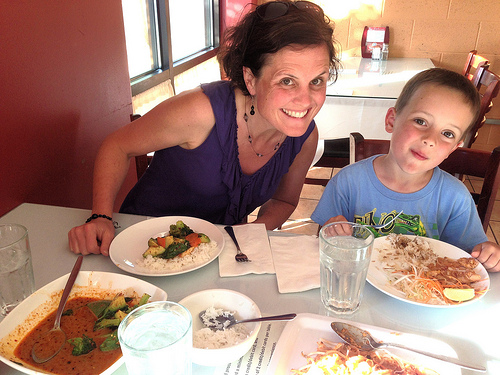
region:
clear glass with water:
[317, 217, 379, 319]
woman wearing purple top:
[82, 1, 332, 252]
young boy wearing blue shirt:
[310, 47, 498, 279]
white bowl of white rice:
[166, 285, 280, 368]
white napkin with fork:
[212, 219, 278, 280]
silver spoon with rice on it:
[192, 300, 305, 335]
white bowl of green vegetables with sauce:
[4, 263, 179, 373]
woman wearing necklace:
[67, 8, 354, 255]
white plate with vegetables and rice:
[107, 201, 234, 286]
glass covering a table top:
[288, 39, 455, 106]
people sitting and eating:
[0, 2, 485, 373]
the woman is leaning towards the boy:
[59, 3, 494, 286]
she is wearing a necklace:
[221, 84, 290, 174]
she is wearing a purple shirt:
[119, 74, 314, 223]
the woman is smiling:
[227, 0, 349, 137]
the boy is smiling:
[372, 59, 481, 181]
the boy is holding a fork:
[309, 191, 403, 247]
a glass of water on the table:
[318, 222, 375, 312]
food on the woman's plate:
[141, 217, 220, 271]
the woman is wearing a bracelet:
[80, 204, 119, 226]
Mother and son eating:
[88, 2, 495, 320]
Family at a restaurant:
[87, 5, 491, 322]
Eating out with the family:
[90, 7, 498, 322]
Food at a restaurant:
[5, 204, 495, 371]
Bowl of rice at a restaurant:
[162, 280, 303, 368]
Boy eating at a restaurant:
[300, 85, 499, 316]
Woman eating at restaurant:
[67, 2, 360, 285]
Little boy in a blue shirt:
[342, 55, 482, 237]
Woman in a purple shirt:
[92, 2, 332, 222]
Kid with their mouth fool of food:
[336, 62, 489, 241]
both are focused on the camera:
[203, 3, 463, 237]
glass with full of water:
[302, 217, 387, 313]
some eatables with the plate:
[390, 239, 475, 306]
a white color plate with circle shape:
[361, 234, 490, 309]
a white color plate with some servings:
[143, 225, 210, 269]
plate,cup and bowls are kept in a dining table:
[51, 230, 498, 368]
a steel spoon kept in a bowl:
[200, 305, 300, 326]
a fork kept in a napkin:
[221, 222, 255, 272]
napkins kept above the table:
[218, 225, 320, 294]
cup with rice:
[198, 289, 270, 355]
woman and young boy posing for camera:
[94, 11, 490, 255]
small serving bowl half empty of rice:
[175, 283, 270, 361]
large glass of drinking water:
[310, 216, 375, 311]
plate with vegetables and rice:
[106, 217, 230, 282]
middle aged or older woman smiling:
[92, 0, 349, 211]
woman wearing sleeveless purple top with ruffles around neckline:
[59, 0, 354, 223]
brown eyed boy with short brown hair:
[334, 58, 486, 231]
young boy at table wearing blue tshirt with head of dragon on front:
[325, 63, 495, 243]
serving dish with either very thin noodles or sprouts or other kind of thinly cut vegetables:
[255, 317, 473, 373]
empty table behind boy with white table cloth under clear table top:
[327, 28, 498, 137]